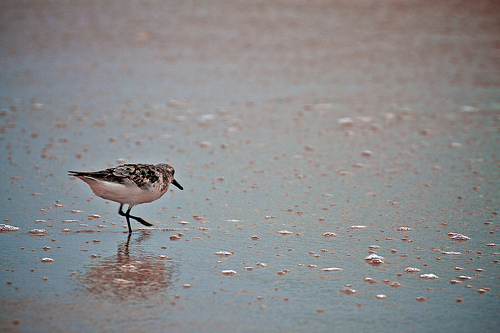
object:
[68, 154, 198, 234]
bird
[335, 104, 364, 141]
bubble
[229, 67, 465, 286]
surface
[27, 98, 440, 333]
ground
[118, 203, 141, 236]
leg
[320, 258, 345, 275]
object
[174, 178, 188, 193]
beak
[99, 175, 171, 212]
bottom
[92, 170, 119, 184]
feather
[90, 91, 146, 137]
water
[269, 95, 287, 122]
sand